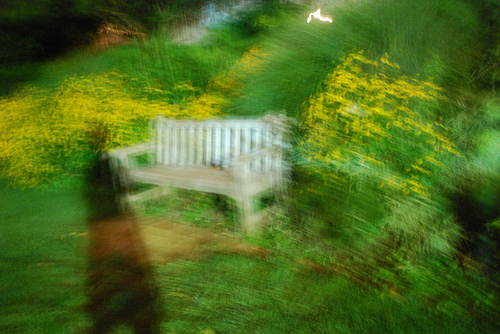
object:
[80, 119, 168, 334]
shadow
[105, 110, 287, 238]
bench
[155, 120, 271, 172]
slats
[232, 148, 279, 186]
right arm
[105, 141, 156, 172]
left arm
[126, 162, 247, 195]
seat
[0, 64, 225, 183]
flowers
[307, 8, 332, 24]
line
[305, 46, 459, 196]
flowers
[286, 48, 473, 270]
bush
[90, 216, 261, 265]
dirt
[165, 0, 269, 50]
house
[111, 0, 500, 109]
grass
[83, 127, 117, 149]
head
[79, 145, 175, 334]
bottom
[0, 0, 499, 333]
garden